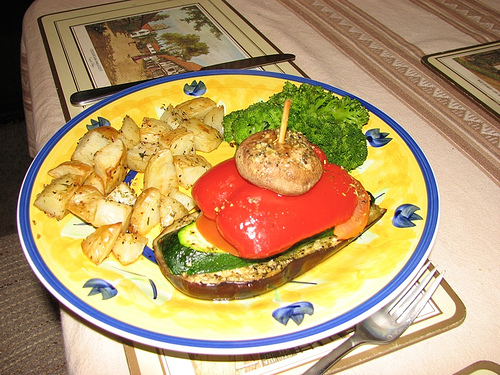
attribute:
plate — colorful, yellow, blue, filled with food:
[17, 69, 440, 356]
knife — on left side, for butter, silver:
[69, 53, 296, 109]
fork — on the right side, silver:
[304, 258, 447, 372]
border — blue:
[19, 74, 441, 350]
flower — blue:
[185, 80, 206, 97]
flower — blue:
[367, 129, 392, 148]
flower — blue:
[394, 204, 423, 229]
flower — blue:
[274, 302, 315, 329]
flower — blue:
[84, 277, 119, 302]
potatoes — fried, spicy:
[35, 97, 224, 268]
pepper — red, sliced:
[192, 144, 358, 261]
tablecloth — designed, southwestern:
[22, 5, 497, 370]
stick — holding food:
[278, 98, 294, 148]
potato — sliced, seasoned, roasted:
[176, 97, 219, 122]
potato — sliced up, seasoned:
[144, 150, 179, 198]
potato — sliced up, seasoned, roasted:
[83, 223, 123, 266]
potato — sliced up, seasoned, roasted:
[34, 178, 82, 223]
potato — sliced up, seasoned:
[92, 139, 129, 198]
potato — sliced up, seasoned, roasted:
[139, 119, 172, 145]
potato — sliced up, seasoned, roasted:
[71, 122, 121, 168]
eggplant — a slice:
[152, 210, 387, 300]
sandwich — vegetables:
[154, 129, 388, 303]